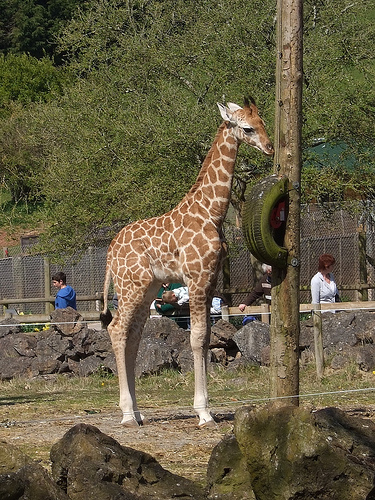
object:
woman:
[310, 254, 337, 316]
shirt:
[310, 272, 337, 315]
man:
[239, 263, 273, 312]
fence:
[0, 243, 375, 382]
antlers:
[243, 95, 256, 108]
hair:
[318, 254, 335, 271]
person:
[233, 263, 272, 316]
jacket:
[240, 274, 271, 306]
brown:
[202, 188, 213, 193]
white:
[152, 269, 162, 274]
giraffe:
[100, 92, 274, 428]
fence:
[0, 201, 375, 315]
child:
[162, 285, 224, 306]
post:
[12, 314, 51, 323]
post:
[270, 0, 305, 406]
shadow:
[135, 406, 366, 426]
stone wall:
[0, 310, 375, 377]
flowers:
[34, 322, 50, 331]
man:
[52, 271, 78, 311]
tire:
[240, 176, 289, 266]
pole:
[268, 0, 300, 404]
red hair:
[318, 253, 336, 272]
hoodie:
[55, 284, 78, 311]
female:
[311, 253, 342, 315]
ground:
[0, 357, 375, 500]